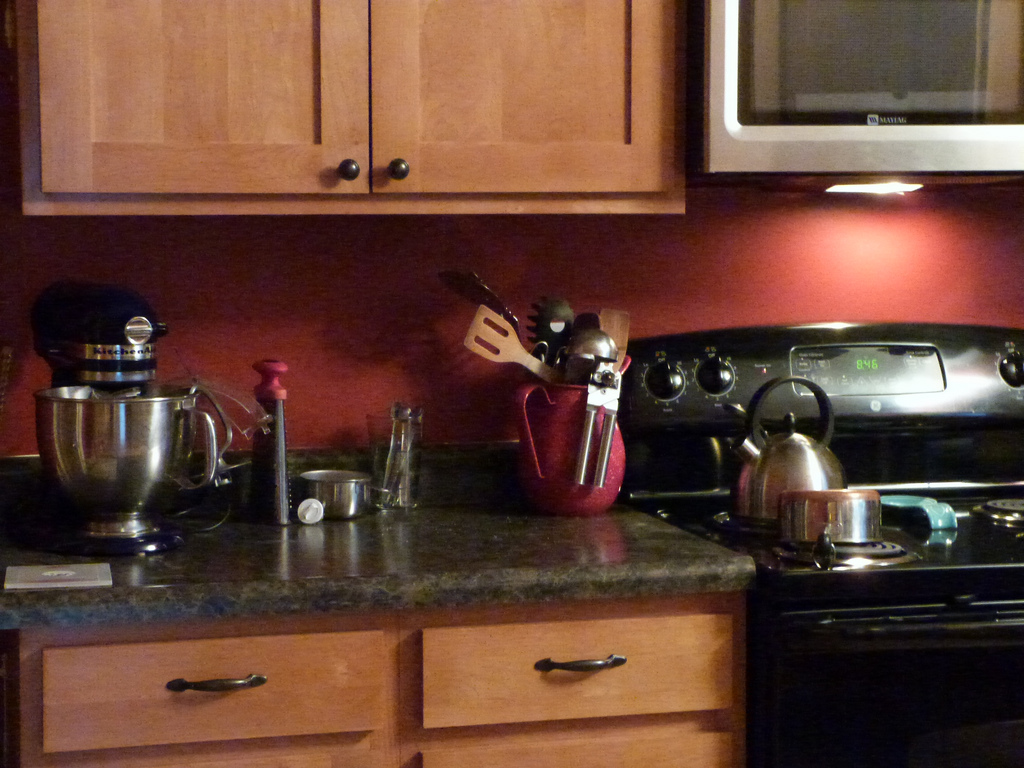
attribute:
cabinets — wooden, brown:
[21, 556, 743, 736]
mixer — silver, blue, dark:
[28, 299, 225, 600]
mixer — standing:
[16, 279, 231, 565]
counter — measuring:
[11, 489, 770, 637]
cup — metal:
[297, 461, 395, 518]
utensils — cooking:
[424, 230, 654, 486]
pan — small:
[772, 482, 902, 562]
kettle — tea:
[726, 371, 847, 551]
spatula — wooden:
[454, 298, 563, 376]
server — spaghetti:
[525, 287, 584, 372]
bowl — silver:
[35, 380, 228, 547]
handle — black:
[529, 646, 625, 683]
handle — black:
[154, 663, 275, 703]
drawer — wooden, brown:
[408, 601, 750, 748]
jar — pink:
[506, 348, 630, 519]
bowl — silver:
[298, 458, 376, 525]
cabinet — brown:
[13, 75, 700, 227]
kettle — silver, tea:
[696, 369, 848, 532]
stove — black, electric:
[618, 313, 1012, 759]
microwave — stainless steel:
[696, 0, 1018, 186]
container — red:
[497, 348, 644, 526]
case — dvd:
[4, 551, 119, 595]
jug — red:
[513, 379, 630, 518]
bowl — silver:
[36, 384, 218, 540]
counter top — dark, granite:
[1, 453, 760, 631]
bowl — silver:
[299, 464, 369, 519]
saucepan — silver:
[781, 483, 888, 572]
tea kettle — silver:
[723, 373, 844, 525]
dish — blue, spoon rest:
[880, 490, 960, 534]